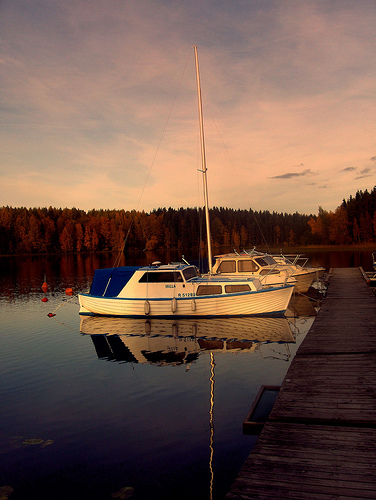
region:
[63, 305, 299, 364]
Boat reflection seen water.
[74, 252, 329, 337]
Three separate boats moored.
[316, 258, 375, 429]
Long wooden dock shown.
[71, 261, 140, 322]
Dark blue tarp boat end.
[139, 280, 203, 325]
Buoys strung boat safety.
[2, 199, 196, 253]
Fall foliage along water.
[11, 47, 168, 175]
Hazy colored sky above.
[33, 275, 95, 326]
Fishing equipment at ready.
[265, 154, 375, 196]
Dark clouds approaching area.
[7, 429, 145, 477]
Pieces of debris lake bottom.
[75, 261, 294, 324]
A boat is floating in the water of a lake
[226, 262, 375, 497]
the boat is at the dock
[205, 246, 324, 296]
a white boat is behind the first boat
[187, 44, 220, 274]
the boat has a tall mast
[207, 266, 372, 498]
It is an old wooden dock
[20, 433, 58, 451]
lily pads float in the water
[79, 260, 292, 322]
the boat is blue and white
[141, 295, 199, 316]
white floats hang from the side of the boat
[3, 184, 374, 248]
there are pine trees behind the boats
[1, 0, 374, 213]
the sky is cloudy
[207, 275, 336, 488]
wooden pier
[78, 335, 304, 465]
shallow lake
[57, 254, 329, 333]
blue and white boat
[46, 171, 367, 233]
early in the morning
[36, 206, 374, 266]
Rural area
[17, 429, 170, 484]
lilypads in the water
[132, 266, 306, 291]
boat is loaded with accessories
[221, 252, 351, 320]
Boats are docked on the pier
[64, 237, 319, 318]
the captain owns these boats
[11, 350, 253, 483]
fish are seen in the water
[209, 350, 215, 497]
mast of the boat is reflected in the water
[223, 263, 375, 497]
three boats next to a wooden pier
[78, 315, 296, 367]
boat is reflected in the water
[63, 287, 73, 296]
red buoys behind the boat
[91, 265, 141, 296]
the back of the boat is blue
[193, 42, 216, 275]
tall mast of boat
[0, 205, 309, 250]
grove of pine trees behind boats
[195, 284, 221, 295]
window on the boat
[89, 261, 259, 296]
cabin of the boat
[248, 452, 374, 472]
the pier is constructed of wood slats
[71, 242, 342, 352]
Boats at the dock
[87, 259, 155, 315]
Blue canopy on the back of the boat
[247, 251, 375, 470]
Wooden dock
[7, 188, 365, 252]
Forest of trees along the lake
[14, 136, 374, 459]
Boats sitting at the dock on a lake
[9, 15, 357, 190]
Blue sky with clouds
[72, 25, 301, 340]
Boat with a tall mast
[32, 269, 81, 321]
Buoys floating in the water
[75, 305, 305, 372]
Reflection of the boat in the water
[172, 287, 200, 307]
Registration number of the boat